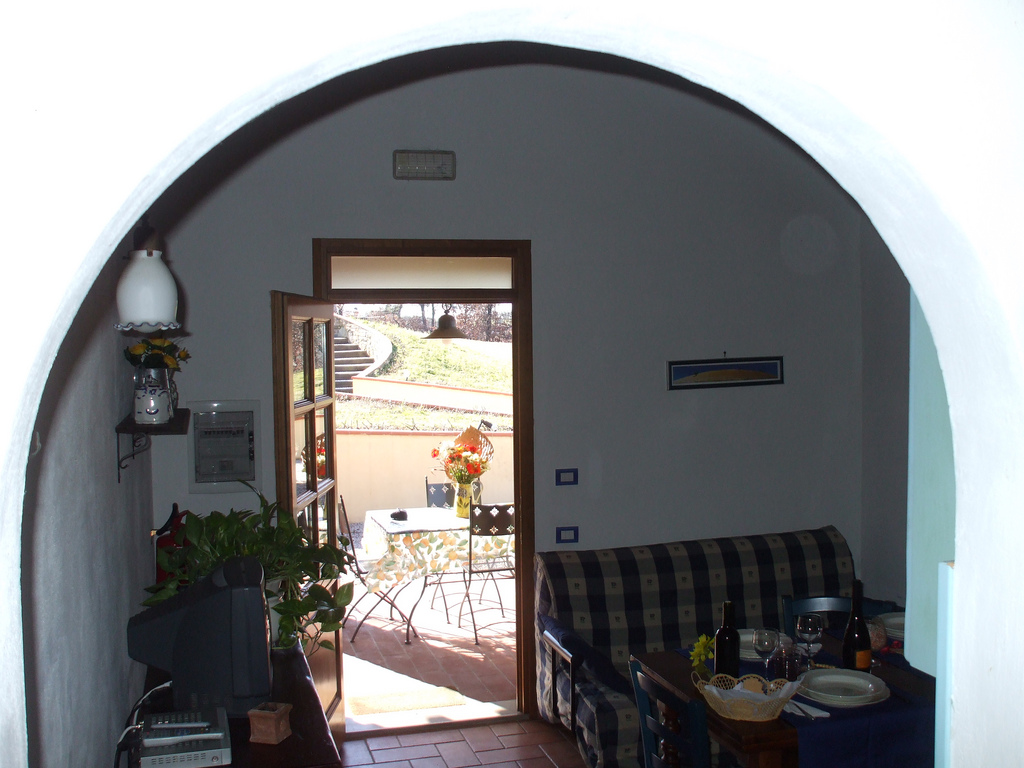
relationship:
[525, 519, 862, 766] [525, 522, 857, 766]
cover on couch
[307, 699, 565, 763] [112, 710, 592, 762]
bricks on floor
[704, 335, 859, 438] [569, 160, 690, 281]
framed picture on wall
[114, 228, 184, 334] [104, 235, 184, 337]
lamp on lamp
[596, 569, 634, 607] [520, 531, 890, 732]
square on couch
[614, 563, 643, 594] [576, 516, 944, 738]
square on couch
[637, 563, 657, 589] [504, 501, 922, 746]
square on couch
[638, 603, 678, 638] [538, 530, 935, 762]
square on couch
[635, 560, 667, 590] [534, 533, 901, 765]
square on couch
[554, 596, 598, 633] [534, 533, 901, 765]
square on couch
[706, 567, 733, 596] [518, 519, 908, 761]
square on couch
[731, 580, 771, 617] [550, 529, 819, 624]
square on couch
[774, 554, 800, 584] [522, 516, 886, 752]
square on couch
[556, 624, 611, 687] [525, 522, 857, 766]
square on couch